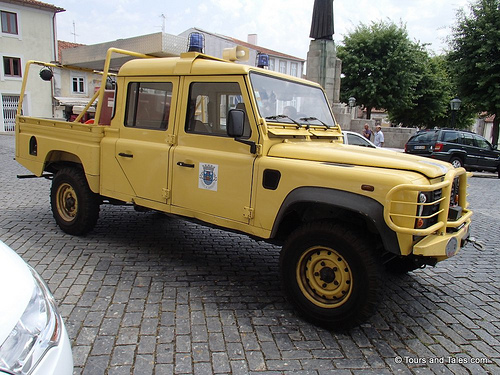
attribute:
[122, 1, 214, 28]
clouds — white 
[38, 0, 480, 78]
sky — blue 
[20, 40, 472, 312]
truck — yellow 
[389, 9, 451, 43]
clouds — white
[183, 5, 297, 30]
sky — blue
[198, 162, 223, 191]
logo — White 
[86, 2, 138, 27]
clouds — white 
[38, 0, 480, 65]
sky — blue 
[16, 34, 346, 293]
truck — yellow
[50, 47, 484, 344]
vehicle — black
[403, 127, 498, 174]
jeep — green 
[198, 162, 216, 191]
decal — white, square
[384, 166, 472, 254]
bumper guard — yellow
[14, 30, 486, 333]
truck — painted, yellow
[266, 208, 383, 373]
tire — black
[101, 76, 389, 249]
truck — yellow 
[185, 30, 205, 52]
light — blue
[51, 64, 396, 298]
truck — yellow , parked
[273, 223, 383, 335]
wheel — yellow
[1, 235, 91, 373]
car — white